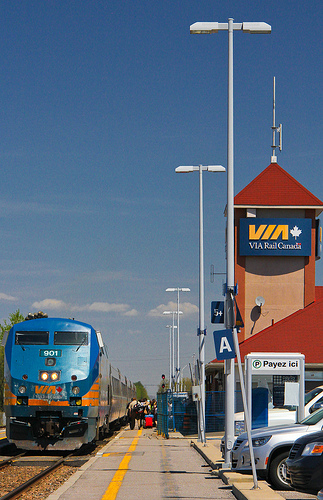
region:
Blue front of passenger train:
[7, 311, 102, 451]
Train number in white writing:
[34, 345, 64, 361]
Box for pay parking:
[246, 344, 305, 425]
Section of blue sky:
[35, 262, 126, 280]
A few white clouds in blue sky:
[7, 284, 173, 315]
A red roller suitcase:
[142, 413, 156, 428]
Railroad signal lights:
[155, 364, 170, 395]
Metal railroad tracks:
[11, 448, 58, 495]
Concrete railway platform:
[116, 428, 203, 498]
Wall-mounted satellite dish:
[246, 286, 272, 313]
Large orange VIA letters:
[248, 223, 291, 240]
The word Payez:
[262, 358, 286, 368]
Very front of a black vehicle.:
[282, 424, 321, 493]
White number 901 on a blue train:
[41, 347, 59, 357]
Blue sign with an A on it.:
[212, 329, 237, 358]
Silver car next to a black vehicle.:
[230, 404, 320, 484]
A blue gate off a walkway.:
[155, 391, 186, 438]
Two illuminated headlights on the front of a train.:
[39, 371, 58, 382]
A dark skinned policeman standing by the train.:
[125, 395, 139, 430]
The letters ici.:
[286, 358, 298, 368]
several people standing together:
[117, 372, 161, 443]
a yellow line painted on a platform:
[108, 435, 146, 497]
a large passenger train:
[29, 309, 154, 495]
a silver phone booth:
[229, 343, 309, 439]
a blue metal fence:
[155, 384, 214, 432]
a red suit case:
[142, 411, 155, 428]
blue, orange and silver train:
[0, 317, 103, 451]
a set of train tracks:
[0, 455, 71, 478]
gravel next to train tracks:
[0, 448, 80, 490]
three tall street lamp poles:
[162, 272, 189, 379]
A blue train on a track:
[4, 279, 125, 456]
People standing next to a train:
[125, 383, 166, 428]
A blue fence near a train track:
[149, 377, 262, 438]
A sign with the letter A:
[210, 325, 240, 365]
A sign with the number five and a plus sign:
[207, 297, 227, 325]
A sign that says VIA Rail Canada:
[237, 216, 314, 260]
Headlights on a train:
[34, 367, 61, 384]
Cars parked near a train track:
[222, 373, 316, 497]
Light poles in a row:
[156, 265, 192, 415]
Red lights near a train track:
[158, 370, 169, 391]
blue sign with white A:
[211, 327, 235, 358]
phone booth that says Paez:
[244, 350, 303, 429]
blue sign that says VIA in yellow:
[237, 217, 310, 256]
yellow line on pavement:
[103, 424, 142, 498]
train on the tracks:
[3, 317, 136, 451]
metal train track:
[2, 450, 63, 498]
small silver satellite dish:
[255, 294, 265, 307]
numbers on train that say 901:
[41, 349, 60, 355]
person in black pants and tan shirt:
[128, 397, 139, 429]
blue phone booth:
[172, 389, 187, 428]